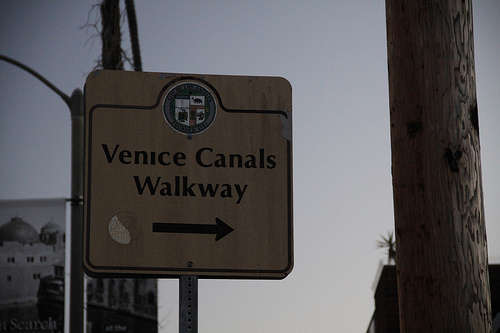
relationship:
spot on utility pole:
[403, 113, 424, 139] [385, 4, 496, 331]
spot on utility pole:
[445, 145, 464, 174] [385, 4, 496, 331]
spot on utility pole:
[464, 100, 487, 135] [385, 4, 496, 331]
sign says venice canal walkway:
[79, 68, 296, 278] [101, 138, 281, 209]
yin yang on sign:
[109, 209, 145, 245] [79, 68, 296, 278]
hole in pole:
[188, 273, 193, 281] [175, 273, 202, 331]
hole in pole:
[185, 309, 197, 316] [175, 273, 202, 331]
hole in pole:
[188, 293, 196, 300] [175, 273, 202, 331]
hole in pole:
[185, 303, 194, 312] [175, 273, 202, 331]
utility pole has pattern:
[385, 4, 496, 331] [451, 12, 471, 95]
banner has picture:
[1, 196, 66, 332] [1, 216, 68, 317]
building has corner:
[368, 253, 500, 331] [367, 251, 402, 298]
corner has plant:
[367, 251, 402, 298] [379, 229, 401, 258]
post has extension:
[68, 81, 88, 332] [1, 51, 71, 110]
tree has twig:
[93, 2, 129, 77] [80, 4, 105, 43]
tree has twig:
[93, 2, 129, 77] [84, 51, 112, 70]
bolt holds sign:
[186, 260, 195, 269] [79, 68, 296, 278]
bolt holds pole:
[186, 260, 195, 269] [175, 273, 202, 331]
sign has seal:
[79, 68, 296, 278] [163, 81, 217, 132]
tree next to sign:
[93, 2, 129, 77] [79, 68, 296, 278]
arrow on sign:
[149, 216, 235, 242] [79, 68, 296, 278]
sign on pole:
[79, 68, 296, 278] [175, 273, 202, 331]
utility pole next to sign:
[385, 4, 496, 331] [79, 68, 296, 278]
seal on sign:
[163, 81, 217, 132] [79, 68, 296, 278]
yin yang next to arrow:
[109, 209, 145, 245] [149, 216, 235, 242]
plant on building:
[379, 229, 401, 258] [368, 253, 500, 331]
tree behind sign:
[93, 2, 129, 77] [79, 68, 296, 278]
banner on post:
[1, 196, 66, 332] [68, 81, 88, 332]